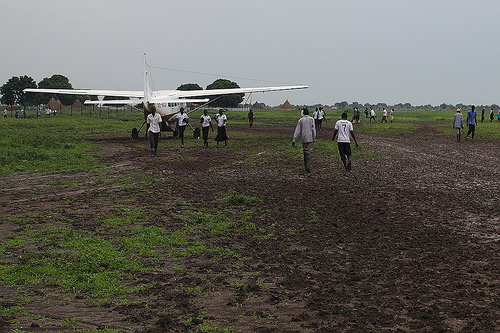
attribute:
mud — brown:
[104, 124, 500, 332]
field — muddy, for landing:
[0, 112, 498, 331]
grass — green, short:
[1, 112, 499, 203]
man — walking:
[290, 107, 319, 171]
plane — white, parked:
[22, 50, 310, 135]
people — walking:
[144, 105, 500, 174]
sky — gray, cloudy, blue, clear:
[1, 0, 498, 106]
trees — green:
[1, 73, 246, 110]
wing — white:
[22, 85, 146, 101]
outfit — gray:
[453, 108, 464, 134]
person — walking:
[453, 107, 463, 141]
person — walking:
[144, 107, 161, 154]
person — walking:
[215, 108, 229, 147]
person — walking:
[175, 108, 191, 144]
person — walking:
[246, 104, 254, 127]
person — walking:
[387, 106, 397, 124]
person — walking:
[318, 107, 325, 127]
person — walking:
[370, 107, 378, 123]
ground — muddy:
[0, 118, 500, 332]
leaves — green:
[1, 75, 79, 101]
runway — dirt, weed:
[0, 114, 267, 280]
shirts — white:
[144, 113, 227, 135]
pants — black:
[145, 118, 366, 160]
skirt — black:
[214, 123, 227, 143]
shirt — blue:
[467, 110, 478, 126]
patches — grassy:
[0, 167, 310, 331]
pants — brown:
[300, 141, 314, 172]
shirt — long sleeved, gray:
[291, 115, 317, 144]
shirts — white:
[176, 110, 229, 128]